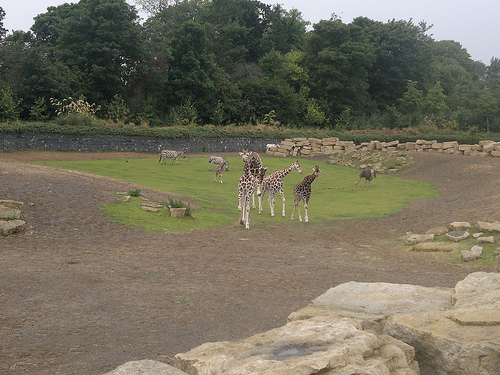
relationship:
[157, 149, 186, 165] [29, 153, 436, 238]
zebra on grass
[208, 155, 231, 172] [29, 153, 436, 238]
zebra on grass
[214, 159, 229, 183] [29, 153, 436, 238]
giraffe on grass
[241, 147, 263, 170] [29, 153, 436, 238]
giraffe on grass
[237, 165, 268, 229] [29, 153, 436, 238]
giraffe on grass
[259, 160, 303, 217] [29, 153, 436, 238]
giraffe on grass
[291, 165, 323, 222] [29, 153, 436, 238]
giraffe on grass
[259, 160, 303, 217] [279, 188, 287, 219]
giraffe has leg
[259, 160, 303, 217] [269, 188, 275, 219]
giraffe has leg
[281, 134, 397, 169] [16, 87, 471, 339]
boulders in park